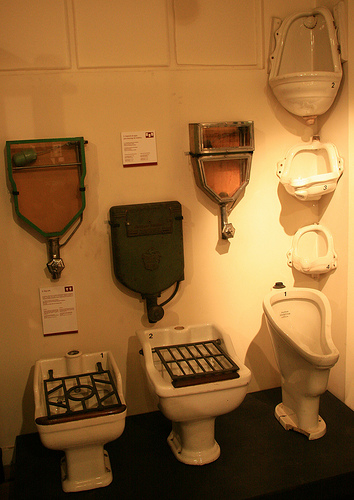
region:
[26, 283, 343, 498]
three bathroom fixtures sitting on floor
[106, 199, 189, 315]
green tank on wall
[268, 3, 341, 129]
urinal highest up on wall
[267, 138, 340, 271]
two small urinals in the corner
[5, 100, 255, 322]
tanks attached to wall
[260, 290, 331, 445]
white tall urinal on the right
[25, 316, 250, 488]
two bathroom fixtures with black parts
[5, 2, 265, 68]
three square panels on the wall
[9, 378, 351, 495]
black box urinals are sitting on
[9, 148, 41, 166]
green piece inside of green and brown tank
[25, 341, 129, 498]
This is a toilet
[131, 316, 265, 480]
This is a toilet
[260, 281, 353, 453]
This is a toilet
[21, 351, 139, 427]
This is a toilet seat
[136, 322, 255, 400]
This is a toilet seat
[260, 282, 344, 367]
This is a toilet seat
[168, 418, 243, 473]
This is a toilet base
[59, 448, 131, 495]
This is a toilet base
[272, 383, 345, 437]
This is a toilet base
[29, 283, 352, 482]
These are toilet seats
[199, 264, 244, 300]
this is the wall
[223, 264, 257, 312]
the wall is white in color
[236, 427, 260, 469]
this is the floor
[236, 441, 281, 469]
the floor is black in color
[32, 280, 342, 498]
these are some toilets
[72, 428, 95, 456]
the bowl is white in color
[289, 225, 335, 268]
this is a urinal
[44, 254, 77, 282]
this is a flush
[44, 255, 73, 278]
the flush is metallic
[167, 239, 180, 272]
the object is green in color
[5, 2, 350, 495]
a room displaying toilets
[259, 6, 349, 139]
a white toilet on corner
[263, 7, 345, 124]
a toilet for men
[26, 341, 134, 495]
a toilet with a grid on top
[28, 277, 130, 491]
a white sign over a toilet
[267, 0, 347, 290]
three toilets on a corner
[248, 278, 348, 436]
a white toilet on the floor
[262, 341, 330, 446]
base of toilet is broken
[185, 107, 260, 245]
small tanks of toilet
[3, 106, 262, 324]
three toilet tanks hang on wall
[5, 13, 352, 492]
a museum display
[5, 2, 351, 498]
a collection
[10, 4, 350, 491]
a collection of urinals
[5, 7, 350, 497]
a collection of men's urinals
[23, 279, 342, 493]
three of the urinals are floor mounted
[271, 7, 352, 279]
three urinals are corner mounted on the wall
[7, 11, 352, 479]
nine urinals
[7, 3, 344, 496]
nine urinals on display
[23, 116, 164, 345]
signs are on the wall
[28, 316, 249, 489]
two of the urinals have metal grates on them